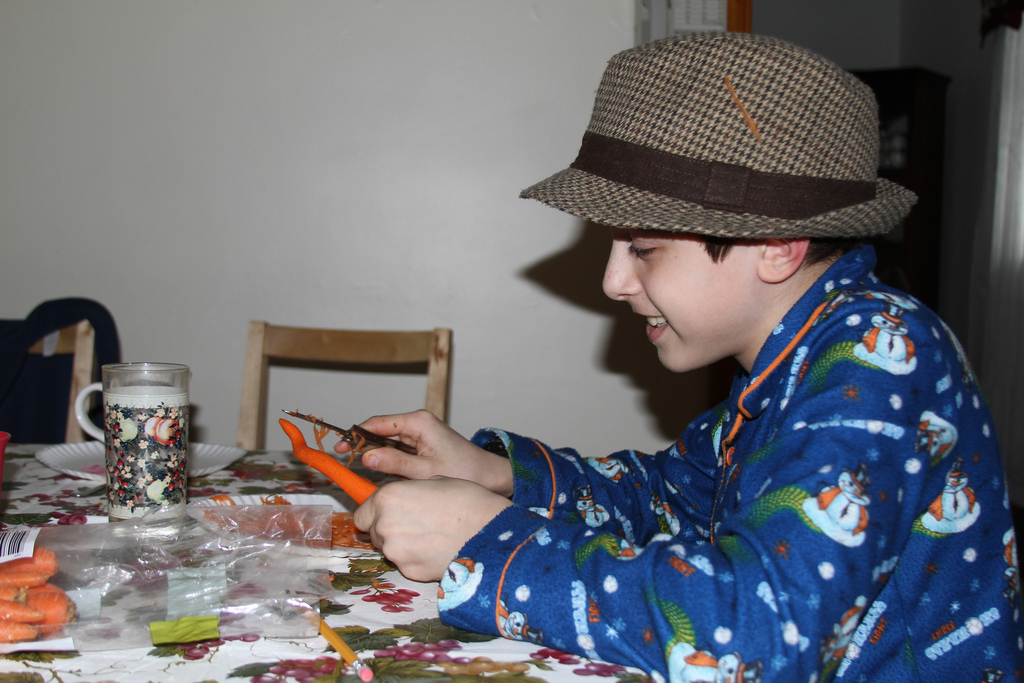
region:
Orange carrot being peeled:
[274, 414, 383, 504]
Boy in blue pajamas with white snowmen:
[338, 26, 1021, 679]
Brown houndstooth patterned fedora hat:
[521, 23, 924, 243]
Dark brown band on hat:
[571, 126, 882, 219]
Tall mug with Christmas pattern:
[76, 357, 194, 532]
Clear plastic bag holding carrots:
[0, 502, 345, 657]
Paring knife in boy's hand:
[283, 404, 421, 458]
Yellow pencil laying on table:
[303, 606, 374, 680]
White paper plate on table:
[34, 433, 249, 487]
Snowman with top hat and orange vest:
[803, 458, 876, 550]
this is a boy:
[287, 11, 1014, 667]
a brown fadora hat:
[499, 11, 942, 310]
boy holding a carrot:
[245, 405, 533, 599]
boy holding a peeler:
[289, 374, 432, 470]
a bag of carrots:
[0, 490, 320, 677]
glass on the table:
[71, 354, 199, 513]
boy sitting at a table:
[62, 22, 1002, 680]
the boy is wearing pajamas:
[346, 209, 1021, 680]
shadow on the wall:
[476, 194, 704, 442]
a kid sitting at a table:
[489, 31, 1014, 679]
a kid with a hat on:
[501, 29, 989, 677]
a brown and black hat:
[522, 38, 900, 238]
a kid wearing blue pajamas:
[404, 48, 1022, 665]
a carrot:
[275, 413, 378, 502]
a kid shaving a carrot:
[268, 75, 1012, 633]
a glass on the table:
[106, 364, 192, 510]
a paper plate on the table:
[34, 436, 241, 479]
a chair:
[245, 319, 462, 449]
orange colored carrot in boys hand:
[270, 413, 408, 503]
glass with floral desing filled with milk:
[82, 357, 200, 520]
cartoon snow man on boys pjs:
[828, 456, 893, 581]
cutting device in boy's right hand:
[280, 386, 452, 459]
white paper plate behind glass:
[53, 423, 99, 481]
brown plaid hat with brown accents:
[558, 44, 926, 256]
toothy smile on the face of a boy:
[634, 307, 701, 358]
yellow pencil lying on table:
[287, 603, 382, 680]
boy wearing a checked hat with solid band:
[362, 23, 1021, 668]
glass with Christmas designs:
[64, 344, 204, 526]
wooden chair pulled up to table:
[226, 307, 462, 441]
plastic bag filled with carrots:
[2, 505, 142, 652]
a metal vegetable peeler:
[277, 382, 437, 456]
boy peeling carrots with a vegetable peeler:
[269, 59, 950, 674]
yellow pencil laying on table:
[267, 591, 400, 680]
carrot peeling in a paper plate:
[198, 484, 379, 555]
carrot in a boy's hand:
[274, 414, 391, 512]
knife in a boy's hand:
[283, 404, 420, 452]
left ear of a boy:
[759, 234, 814, 289]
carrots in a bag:
[8, 521, 76, 648]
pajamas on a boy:
[453, 325, 1001, 680]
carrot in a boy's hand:
[296, 420, 380, 509]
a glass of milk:
[72, 344, 190, 534]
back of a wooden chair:
[251, 317, 464, 455]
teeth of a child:
[641, 291, 677, 346]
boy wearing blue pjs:
[322, 11, 1013, 679]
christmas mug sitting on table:
[65, 346, 227, 559]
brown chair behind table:
[232, 291, 480, 479]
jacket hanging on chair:
[2, 282, 116, 448]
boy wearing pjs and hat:
[324, 11, 996, 679]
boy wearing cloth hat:
[504, 46, 928, 265]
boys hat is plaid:
[516, 25, 918, 275]